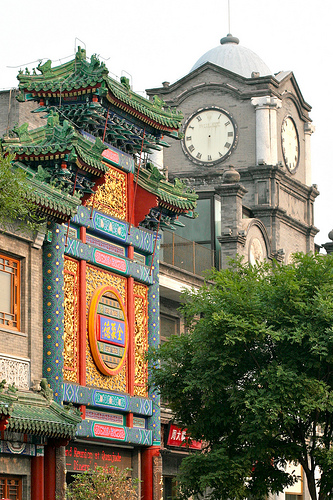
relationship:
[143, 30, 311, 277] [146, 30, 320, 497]
clock tower on building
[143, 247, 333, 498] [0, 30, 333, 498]
tree in front of buildings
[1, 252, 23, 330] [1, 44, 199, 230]
window below roof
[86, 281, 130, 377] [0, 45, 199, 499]
sign on building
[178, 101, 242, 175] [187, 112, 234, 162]
clocks has roman numerals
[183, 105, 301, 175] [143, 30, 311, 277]
clocks on clock tower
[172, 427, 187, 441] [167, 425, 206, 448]
asian print on asian print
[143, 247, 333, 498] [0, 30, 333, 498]
tree across from buildings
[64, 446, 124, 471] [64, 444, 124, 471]
text on text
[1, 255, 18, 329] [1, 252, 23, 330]
frame on window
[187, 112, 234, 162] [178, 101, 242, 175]
roman numerals on clocks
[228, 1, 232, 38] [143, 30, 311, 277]
pole on clock tower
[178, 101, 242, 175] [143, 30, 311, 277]
clocks on clock tower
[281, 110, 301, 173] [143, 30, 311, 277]
clock on clock tower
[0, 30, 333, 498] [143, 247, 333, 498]
buildings behind tree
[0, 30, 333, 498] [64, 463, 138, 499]
buildings behind tree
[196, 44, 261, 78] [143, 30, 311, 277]
dome on clock tower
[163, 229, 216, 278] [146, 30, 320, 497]
fence on building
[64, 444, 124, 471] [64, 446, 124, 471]
text has text